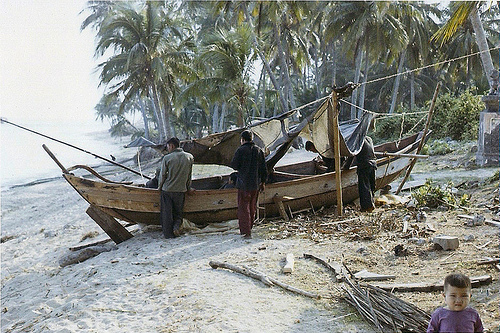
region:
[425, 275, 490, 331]
boy in a purple shirt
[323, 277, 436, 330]
bundle of wood on the beach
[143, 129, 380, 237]
group of men working on the sail boat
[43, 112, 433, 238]
wooden boat on the beach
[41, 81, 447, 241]
wooden boat for fishing in the ocean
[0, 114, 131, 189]
calm light blue body of water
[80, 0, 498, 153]
group of trees on the beach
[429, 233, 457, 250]
gray brick on the beach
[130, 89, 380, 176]
gray sail for the fishing boat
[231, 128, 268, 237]
man in a black jacket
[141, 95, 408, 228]
three men standing by a boat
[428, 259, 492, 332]
a young boy with short hair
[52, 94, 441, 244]
a wood boat on land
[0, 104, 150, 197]
a large body of water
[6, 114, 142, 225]
the shore by the ocean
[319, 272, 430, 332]
tree branches in a pile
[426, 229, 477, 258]
a large brick on the ground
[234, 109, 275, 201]
a man wearing a black shirt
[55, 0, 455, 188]
several palm trees by the ocean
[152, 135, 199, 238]
a man wearing black pants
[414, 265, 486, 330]
a child wearing a purple shirt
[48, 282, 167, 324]
white sand of the beach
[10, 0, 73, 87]
white skies over the ocean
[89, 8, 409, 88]
several palm trees growing on the beach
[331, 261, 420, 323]
a bundle of sticks on the beach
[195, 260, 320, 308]
a branch lying on the sand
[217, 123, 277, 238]
a man wearing a black shirt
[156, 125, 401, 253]
three people next to a boat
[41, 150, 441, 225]
a wooden boat on the beach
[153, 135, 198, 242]
a man in a grey shirt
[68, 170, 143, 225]
this is a boat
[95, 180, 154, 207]
the boat is parked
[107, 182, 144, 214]
the boat is wooden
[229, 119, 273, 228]
this is a man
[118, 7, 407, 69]
these are palm trees beside the boat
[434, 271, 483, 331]
this is a child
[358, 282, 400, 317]
these are firewoods on the ground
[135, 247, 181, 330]
the place is full of beach sand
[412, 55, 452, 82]
this is a rope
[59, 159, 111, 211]
the front is sharp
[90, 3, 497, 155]
A lot of palm trees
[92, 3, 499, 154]
A forest of palm trees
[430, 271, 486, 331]
A small boy with short dark hair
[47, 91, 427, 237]
An old wooden boat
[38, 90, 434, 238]
A boat sitting on a beach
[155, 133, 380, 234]
Three people on a beach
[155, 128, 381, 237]
Three people looking at a old boat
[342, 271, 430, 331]
A small pile of sticks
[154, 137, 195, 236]
A man in a tan shirt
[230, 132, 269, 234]
A man in black with brown pants